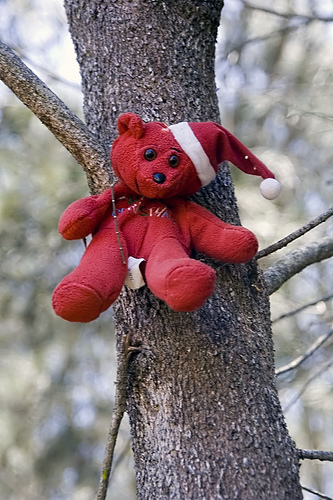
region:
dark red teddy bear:
[52, 109, 288, 321]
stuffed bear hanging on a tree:
[33, 99, 288, 329]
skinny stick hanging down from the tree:
[94, 342, 147, 497]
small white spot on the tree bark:
[241, 454, 250, 466]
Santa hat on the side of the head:
[167, 101, 289, 207]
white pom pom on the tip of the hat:
[254, 175, 282, 201]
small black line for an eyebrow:
[171, 145, 186, 153]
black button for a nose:
[150, 167, 167, 186]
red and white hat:
[167, 119, 289, 202]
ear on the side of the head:
[115, 111, 147, 133]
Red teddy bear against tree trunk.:
[0, 0, 321, 495]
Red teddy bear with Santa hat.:
[47, 107, 274, 316]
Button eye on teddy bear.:
[167, 153, 176, 164]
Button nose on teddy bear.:
[150, 168, 162, 180]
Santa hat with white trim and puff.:
[165, 116, 277, 195]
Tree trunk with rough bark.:
[119, 322, 294, 493]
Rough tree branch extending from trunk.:
[0, 37, 84, 168]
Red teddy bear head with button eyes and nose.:
[109, 110, 200, 195]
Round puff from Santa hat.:
[255, 176, 279, 197]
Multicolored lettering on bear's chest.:
[113, 193, 171, 221]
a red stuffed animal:
[20, 94, 297, 328]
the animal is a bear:
[66, 110, 279, 331]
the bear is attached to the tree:
[32, 96, 281, 315]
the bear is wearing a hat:
[83, 88, 298, 207]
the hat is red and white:
[176, 106, 296, 206]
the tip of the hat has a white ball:
[250, 164, 290, 212]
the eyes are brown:
[133, 137, 183, 170]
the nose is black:
[143, 168, 174, 189]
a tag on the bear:
[106, 228, 152, 306]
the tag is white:
[114, 250, 161, 301]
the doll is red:
[60, 112, 280, 345]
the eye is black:
[165, 145, 182, 170]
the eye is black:
[143, 151, 157, 160]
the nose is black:
[147, 170, 166, 182]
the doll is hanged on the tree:
[38, 130, 249, 326]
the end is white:
[262, 179, 283, 202]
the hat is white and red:
[175, 129, 215, 183]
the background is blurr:
[10, 179, 58, 316]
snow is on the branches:
[287, 229, 331, 266]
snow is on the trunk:
[137, 399, 193, 471]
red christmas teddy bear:
[44, 112, 285, 329]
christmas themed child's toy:
[38, 110, 297, 332]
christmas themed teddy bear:
[49, 101, 290, 334]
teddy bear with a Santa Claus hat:
[45, 88, 291, 352]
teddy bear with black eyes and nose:
[52, 91, 287, 343]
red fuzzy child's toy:
[42, 94, 291, 363]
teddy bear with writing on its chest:
[41, 85, 291, 339]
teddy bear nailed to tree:
[45, 71, 297, 399]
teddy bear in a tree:
[48, 95, 292, 343]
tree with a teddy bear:
[1, 0, 330, 497]